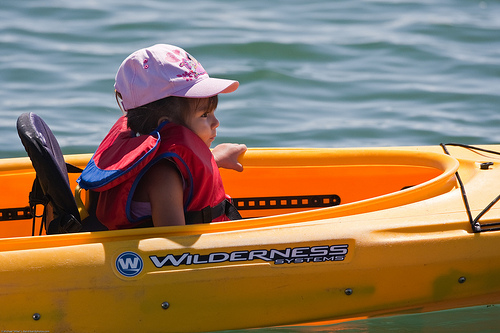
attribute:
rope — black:
[440, 141, 498, 233]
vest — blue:
[104, 119, 232, 215]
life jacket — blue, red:
[75, 126, 230, 213]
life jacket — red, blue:
[77, 112, 243, 229]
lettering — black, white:
[100, 240, 379, 282]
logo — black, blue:
[116, 248, 141, 275]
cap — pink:
[112, 44, 240, 113]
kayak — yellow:
[2, 120, 499, 330]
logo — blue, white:
[112, 244, 141, 275]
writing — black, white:
[145, 245, 350, 267]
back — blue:
[11, 109, 86, 223]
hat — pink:
[99, 34, 254, 130]